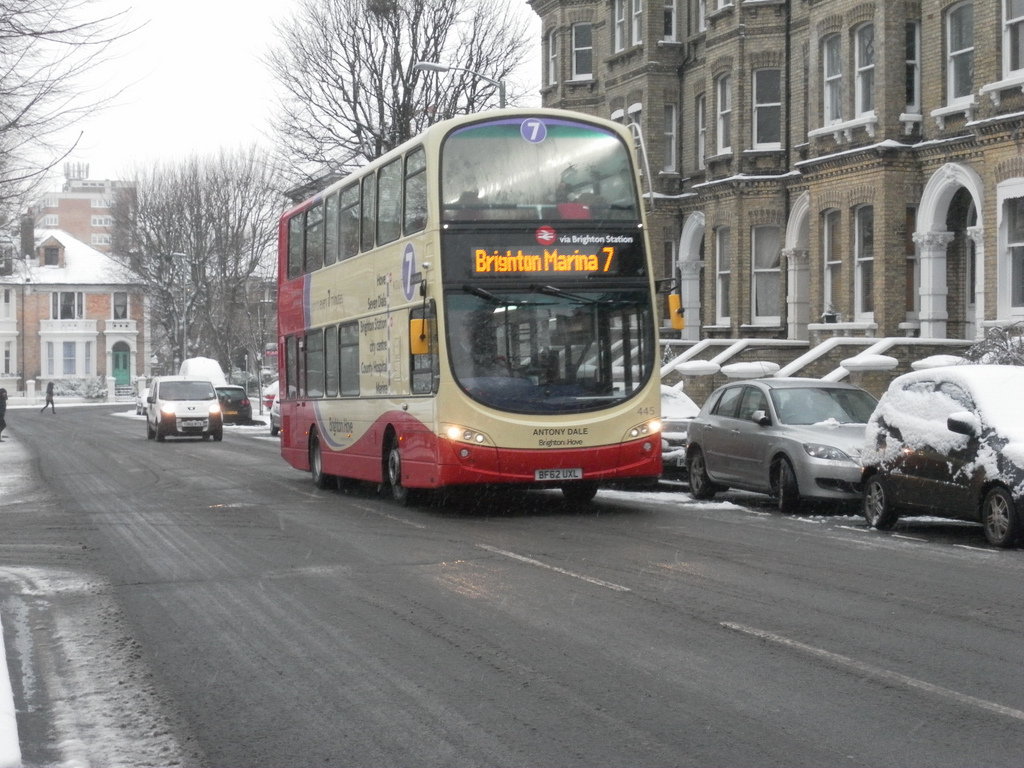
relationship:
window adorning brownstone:
[694, 87, 712, 167] [670, 5, 798, 418]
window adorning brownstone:
[709, 65, 736, 158] [696, 1, 802, 408]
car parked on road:
[676, 376, 884, 519] [2, 402, 1018, 768]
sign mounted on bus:
[467, 243, 625, 274] [272, 104, 670, 504]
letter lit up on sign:
[473, 243, 489, 272] [467, 243, 625, 274]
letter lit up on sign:
[486, 256, 495, 272] [467, 243, 625, 274]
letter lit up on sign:
[497, 253, 508, 271] [467, 243, 625, 274]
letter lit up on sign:
[540, 245, 560, 272] [467, 243, 625, 274]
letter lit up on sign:
[586, 253, 600, 273] [467, 243, 625, 274]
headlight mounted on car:
[160, 404, 178, 417] [143, 370, 226, 444]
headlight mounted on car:
[207, 404, 225, 417] [143, 370, 226, 444]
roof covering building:
[4, 223, 154, 284] [4, 208, 156, 405]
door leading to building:
[110, 340, 134, 388] [0, 213, 158, 401]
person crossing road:
[39, 380, 56, 413] [2, 402, 1018, 768]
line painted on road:
[475, 538, 635, 593] [2, 402, 1018, 765]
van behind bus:
[136, 366, 232, 453] [227, 96, 683, 486]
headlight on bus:
[440, 414, 473, 454] [272, 104, 670, 504]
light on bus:
[637, 407, 685, 468] [240, 100, 707, 494]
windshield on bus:
[453, 251, 650, 398] [272, 104, 670, 504]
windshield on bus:
[423, 217, 678, 406] [248, 81, 691, 514]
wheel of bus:
[302, 434, 328, 482] [272, 104, 670, 504]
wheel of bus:
[385, 440, 403, 508] [272, 104, 670, 504]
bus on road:
[272, 104, 670, 504] [2, 402, 1018, 768]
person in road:
[39, 380, 56, 413] [2, 402, 1018, 768]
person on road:
[37, 380, 61, 417] [2, 402, 1018, 765]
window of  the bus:
[314, 178, 369, 254] [250, 76, 640, 511]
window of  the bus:
[341, 161, 387, 255] [272, 104, 670, 504]